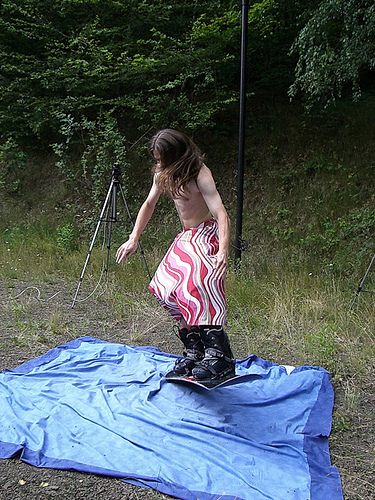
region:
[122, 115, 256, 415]
person in black boots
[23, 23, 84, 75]
green leaves in brown trees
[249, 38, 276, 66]
green leaves in brown trees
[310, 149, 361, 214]
green leaves in brown trees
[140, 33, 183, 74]
green leaves in brown trees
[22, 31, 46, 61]
green leaves in brown trees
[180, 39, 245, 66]
green leaves in brown trees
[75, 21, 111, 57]
green leaves in brown trees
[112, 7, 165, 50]
green leaves in brown trees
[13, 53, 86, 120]
green leaves in brown trees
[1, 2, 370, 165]
green leaves on trees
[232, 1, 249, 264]
black pole in grass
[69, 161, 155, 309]
camera tripod on grass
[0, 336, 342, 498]
wrinkles in blue blanket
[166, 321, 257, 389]
boots on tilted snowboard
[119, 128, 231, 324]
shirtless man in skirt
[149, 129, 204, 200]
long hair over shoulder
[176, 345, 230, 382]
buckles on snow boots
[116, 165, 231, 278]
two extended arms of man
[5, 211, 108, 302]
wire hanging from tripod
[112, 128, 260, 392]
Man riding a snowboard on a blue mat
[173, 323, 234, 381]
Black snowboard boots on man's feet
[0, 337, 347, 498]
Blue tarp on the ground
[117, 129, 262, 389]
Man wearing a skirt and riding a snowboard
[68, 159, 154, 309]
Tripod to left of man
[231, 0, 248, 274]
Black post extending from ground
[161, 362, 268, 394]
Nose of snowboard pointing up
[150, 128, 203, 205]
Man with long brown hair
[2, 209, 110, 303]
Electrical cord for tri-pod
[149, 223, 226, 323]
Colorful striped skirt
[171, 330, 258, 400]
black roller blades on blue blanket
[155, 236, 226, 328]
red and white striped dress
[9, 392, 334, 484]
blue blanket on the ground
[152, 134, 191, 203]
long hair on person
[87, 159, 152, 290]
tri pod in back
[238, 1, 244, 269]
pole behind the boy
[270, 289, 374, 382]
tall grass in the field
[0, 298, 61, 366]
stones on the ground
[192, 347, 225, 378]
buckles on the boots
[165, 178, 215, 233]
no shirt on the chest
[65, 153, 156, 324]
A camera tripod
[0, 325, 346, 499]
A blue sheet on the ground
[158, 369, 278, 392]
A snowboard in the air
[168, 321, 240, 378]
A pair of snow boots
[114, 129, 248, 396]
A man on a snowboard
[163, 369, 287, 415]
Snowboard on a blanket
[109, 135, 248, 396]
A shirtless man outdoors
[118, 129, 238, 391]
Man wearing a long skit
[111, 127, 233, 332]
Man with long hair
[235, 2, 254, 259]
A long black pole